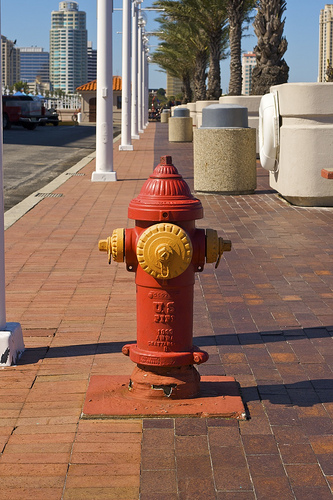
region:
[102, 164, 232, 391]
a fire hydrant on a sidewalk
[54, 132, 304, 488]
a brick sidewalk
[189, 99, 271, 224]
a stone-edged trash can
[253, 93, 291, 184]
a decorative life ring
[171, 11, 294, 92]
a row of palm trees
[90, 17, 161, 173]
a row of light poles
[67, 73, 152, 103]
an orange roof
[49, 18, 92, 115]
a skyscraper in the distance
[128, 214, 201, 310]
an orange cap on a fire hydrant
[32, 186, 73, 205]
a drainage grate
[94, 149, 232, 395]
a fire hydrant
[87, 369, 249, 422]
paint chipping off base of fire hydrant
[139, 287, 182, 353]
raised text on fire hydrant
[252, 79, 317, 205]
life preserver design on cement structure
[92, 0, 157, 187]
white poles set in sidewalk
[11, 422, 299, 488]
sidewalk paved in red bricks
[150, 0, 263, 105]
row of palm trees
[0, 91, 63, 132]
parked vehicles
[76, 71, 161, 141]
small structure near sidewalk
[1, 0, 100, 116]
buildings in the distance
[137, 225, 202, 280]
yellow metal hose portal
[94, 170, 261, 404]
red and yellow fire hydrant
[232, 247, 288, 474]
dark red exposed brick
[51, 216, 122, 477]
light red classic brick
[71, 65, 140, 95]
orange terra cotta roof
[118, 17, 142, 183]
row of white metal poles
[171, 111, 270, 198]
concrete cylinder stones on ground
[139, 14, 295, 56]
tall green and brown palm trees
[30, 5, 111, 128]
gray and blue glass building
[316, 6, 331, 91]
tall tan office building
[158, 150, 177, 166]
a bolt on the fire hydrant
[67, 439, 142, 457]
a red brick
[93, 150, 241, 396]
a red and yellow fire hydrant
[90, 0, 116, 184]
a white metal pole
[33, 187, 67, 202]
a grate on the street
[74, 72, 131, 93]
an orange roof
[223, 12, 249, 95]
the brown trunk of a tree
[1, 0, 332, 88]
a clear blue sky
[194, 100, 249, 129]
a gray trash can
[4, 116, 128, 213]
a gray asphalt road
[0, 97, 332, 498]
the promenade at the waterfront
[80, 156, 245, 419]
a red and yellow fire hydrant on the walkway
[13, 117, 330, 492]
the walkway is red brick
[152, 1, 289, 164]
date palms line the walkway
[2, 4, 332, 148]
tall buildings surround the walk in the distance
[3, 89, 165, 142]
vehicles are parked near the walkway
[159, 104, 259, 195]
cement trash cans line the sidewalk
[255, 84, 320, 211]
a life preserver is hanging from a cement wall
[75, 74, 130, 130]
the house has a barrel tiled roof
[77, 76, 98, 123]
the house has an arched wooden door